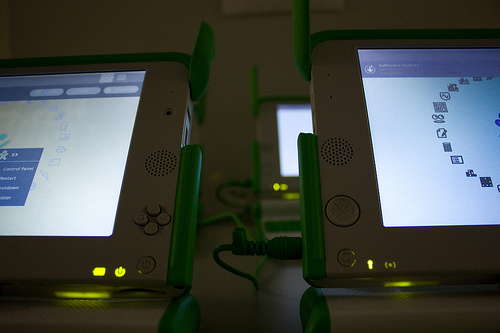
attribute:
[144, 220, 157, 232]
button — control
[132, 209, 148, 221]
button — control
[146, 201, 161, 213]
button — control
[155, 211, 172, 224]
button — control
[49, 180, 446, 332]
desk — is wood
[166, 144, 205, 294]
part — is green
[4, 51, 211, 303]
monitor — lit up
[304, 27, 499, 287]
screen — part 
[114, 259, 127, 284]
button — power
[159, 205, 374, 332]
desk — white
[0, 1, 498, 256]
wall — white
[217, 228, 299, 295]
cord — green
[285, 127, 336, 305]
attachment — green, plastic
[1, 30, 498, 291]
systems — illuminated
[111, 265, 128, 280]
power indicator — green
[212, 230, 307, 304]
wire — green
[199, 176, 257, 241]
wire — green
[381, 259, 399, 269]
power light — green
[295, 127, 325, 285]
side bar — green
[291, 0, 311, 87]
side bar — green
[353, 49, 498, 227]
monitor screen — computer monitor 